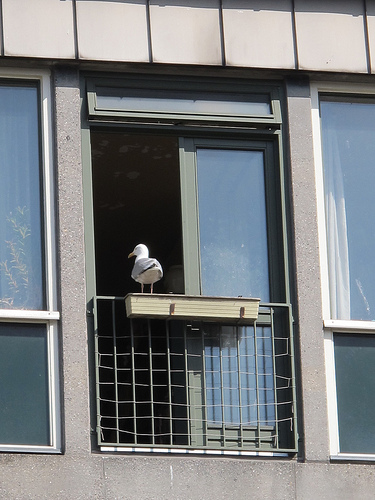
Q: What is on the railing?
A: Seagull.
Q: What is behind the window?
A: Curtain.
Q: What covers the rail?
A: Grates.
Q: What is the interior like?
A: Dark.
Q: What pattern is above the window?
A: Tile.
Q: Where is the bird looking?
A: Inside the building.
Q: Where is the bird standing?
A: On the flower box.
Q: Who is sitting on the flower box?
A: A seagull.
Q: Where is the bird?
A: In the flower box.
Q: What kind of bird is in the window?
A: A seagull.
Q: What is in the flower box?
A: A seagull.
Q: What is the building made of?
A: Concrete.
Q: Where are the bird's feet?
A: Inside the flower box.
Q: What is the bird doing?
A: Standing on a plant tray.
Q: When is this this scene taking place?
A: Day time.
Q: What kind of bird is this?
A: Seagull.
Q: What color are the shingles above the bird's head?
A: Brown.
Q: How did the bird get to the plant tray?
A: Flew.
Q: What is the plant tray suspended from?
A: Small gate.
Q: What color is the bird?
A: White and black.